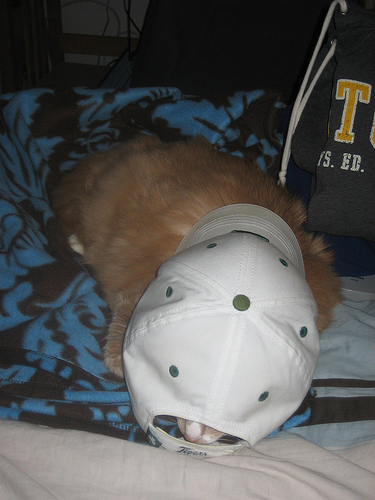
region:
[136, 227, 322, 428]
Cat wearing a white hat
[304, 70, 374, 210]
Grey tennis shirt on bed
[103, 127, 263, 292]
brown cat on a bed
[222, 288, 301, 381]
Green and white hat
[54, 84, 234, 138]
Blue and brown blanket on bed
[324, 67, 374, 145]
Yellow letters on a shirt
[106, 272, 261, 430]
Cats head under a hat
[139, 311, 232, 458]
Cats head under a hat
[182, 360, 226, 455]
Cats head under a hat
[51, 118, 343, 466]
a cat wearing a cap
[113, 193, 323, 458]
a white cap on cat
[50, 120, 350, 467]
cat is color brown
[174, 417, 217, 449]
nose of cat is white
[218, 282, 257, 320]
button on top is gray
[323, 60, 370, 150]
a letter T in a bag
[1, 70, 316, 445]
a cat under a comforter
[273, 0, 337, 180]
a white string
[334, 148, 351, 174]
a letter E in a bag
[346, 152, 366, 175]
a letter D in a bag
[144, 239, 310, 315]
Hat on top on a cat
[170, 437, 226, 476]
Word tiger on a hat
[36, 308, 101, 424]
brown and blue floral blanket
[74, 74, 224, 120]
brown and blue floral blanket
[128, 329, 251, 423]
cat head under a cap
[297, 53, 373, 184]
Letter T on a shirt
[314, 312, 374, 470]
white sheet on a sofa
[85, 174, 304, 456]
Cat laying on a futon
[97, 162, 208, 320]
brown cat on the bed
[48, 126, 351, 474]
An animal on a bed.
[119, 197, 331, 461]
A white ball cap.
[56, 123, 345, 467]
A hat on an animal.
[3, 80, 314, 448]
A brown and blue blanket on a bed.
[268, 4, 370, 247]
A hoodie beside an animal.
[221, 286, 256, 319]
A green button on a white hat.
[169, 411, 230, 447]
The tip of an animal's nose.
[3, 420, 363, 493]
A white blanket on a bed.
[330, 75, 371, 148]
The letter "T".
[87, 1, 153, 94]
Black cords against a wall.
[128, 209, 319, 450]
white baseball hat on top of cat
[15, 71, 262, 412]
brown blanket with blue floral design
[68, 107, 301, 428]
tan cat laying on top of blanket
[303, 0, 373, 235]
grey seatshirt folded on bed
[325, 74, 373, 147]
yellow T with a white outline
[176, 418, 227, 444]
cat's nose showing through hat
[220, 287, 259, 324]
green button on top of baseball hat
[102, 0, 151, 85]
black wires in the background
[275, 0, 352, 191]
white strings on sweatshirt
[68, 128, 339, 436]
cat sleeping on a bed